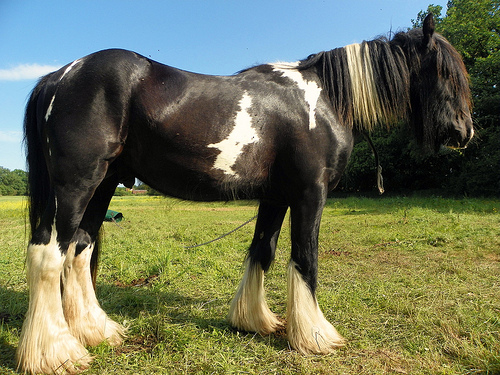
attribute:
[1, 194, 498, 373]
field — white , black 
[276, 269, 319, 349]
hoof — hairy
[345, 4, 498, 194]
trees — green 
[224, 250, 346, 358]
long hair — white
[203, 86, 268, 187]
spot — white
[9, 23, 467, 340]
horse — black , white 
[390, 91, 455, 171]
ground — black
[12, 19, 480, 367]
horse — black , white 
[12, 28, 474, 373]
pony — side, standing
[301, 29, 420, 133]
mane — blonde 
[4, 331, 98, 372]
hoof — hairy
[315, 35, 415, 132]
mane — white